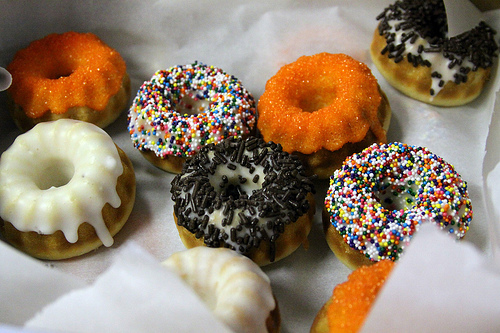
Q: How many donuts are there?
A: 9.